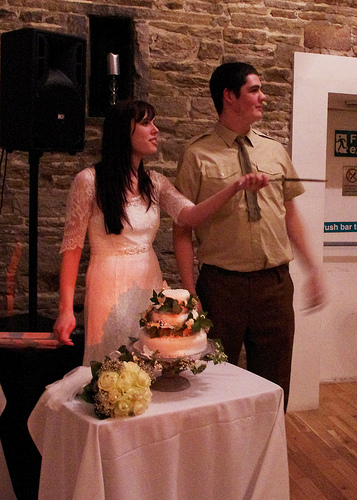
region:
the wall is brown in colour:
[169, 14, 212, 39]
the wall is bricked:
[164, 13, 197, 100]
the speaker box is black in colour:
[6, 25, 86, 152]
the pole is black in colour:
[27, 146, 47, 324]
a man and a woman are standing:
[91, 50, 332, 321]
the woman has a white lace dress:
[87, 191, 156, 290]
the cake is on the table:
[52, 267, 237, 440]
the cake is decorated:
[122, 278, 245, 389]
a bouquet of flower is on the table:
[75, 355, 152, 431]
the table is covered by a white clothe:
[40, 373, 308, 493]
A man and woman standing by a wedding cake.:
[53, 60, 327, 415]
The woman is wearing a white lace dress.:
[59, 164, 194, 364]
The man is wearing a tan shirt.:
[177, 121, 304, 272]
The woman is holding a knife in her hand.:
[234, 171, 330, 192]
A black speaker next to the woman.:
[2, 31, 84, 149]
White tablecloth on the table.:
[25, 359, 286, 497]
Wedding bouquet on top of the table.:
[72, 357, 152, 417]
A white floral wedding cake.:
[137, 287, 206, 356]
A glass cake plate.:
[129, 340, 213, 391]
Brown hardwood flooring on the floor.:
[284, 379, 356, 498]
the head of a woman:
[86, 99, 168, 193]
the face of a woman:
[71, 103, 183, 183]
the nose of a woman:
[139, 120, 160, 143]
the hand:
[37, 287, 97, 371]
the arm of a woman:
[32, 155, 115, 334]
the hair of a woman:
[80, 63, 176, 183]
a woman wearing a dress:
[33, 72, 194, 330]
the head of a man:
[216, 45, 290, 139]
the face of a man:
[194, 32, 286, 153]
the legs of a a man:
[181, 234, 328, 450]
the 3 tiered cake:
[136, 287, 207, 355]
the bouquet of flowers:
[81, 356, 149, 418]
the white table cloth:
[26, 354, 289, 497]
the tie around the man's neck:
[235, 134, 261, 222]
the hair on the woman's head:
[92, 98, 157, 234]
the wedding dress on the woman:
[58, 165, 195, 367]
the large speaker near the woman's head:
[1, 28, 86, 153]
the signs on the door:
[323, 128, 355, 231]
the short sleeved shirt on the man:
[174, 120, 304, 269]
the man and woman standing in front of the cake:
[54, 60, 327, 414]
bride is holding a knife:
[239, 173, 316, 209]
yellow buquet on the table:
[78, 358, 157, 415]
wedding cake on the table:
[126, 285, 226, 395]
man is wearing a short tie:
[234, 134, 269, 226]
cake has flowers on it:
[144, 277, 224, 398]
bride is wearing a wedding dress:
[72, 139, 189, 382]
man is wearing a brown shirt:
[192, 124, 323, 370]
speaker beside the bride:
[6, 17, 93, 155]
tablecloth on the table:
[56, 334, 317, 499]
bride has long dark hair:
[112, 83, 171, 242]